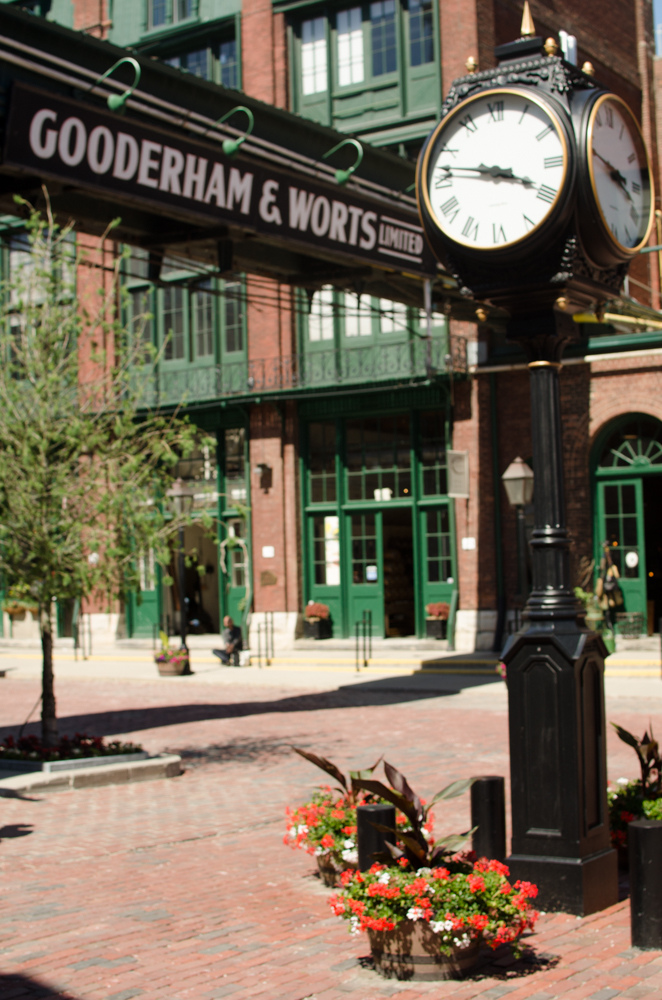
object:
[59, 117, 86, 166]
letter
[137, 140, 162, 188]
letter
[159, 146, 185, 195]
letter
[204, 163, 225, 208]
letter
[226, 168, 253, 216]
letter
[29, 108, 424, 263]
sign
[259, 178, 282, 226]
letter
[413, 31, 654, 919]
clock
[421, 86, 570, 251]
face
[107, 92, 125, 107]
light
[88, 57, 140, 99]
pole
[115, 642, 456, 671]
stairs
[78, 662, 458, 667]
edge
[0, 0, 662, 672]
background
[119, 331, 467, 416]
railing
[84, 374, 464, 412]
edge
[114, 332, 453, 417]
balcony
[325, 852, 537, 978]
flowers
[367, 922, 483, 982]
pot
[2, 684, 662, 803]
street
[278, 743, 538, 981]
lot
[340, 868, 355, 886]
flower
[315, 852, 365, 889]
pot